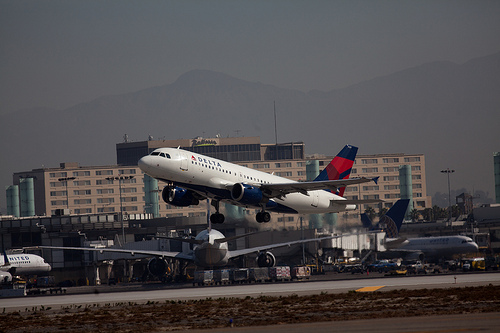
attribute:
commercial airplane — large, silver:
[22, 213, 384, 270]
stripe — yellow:
[353, 281, 385, 296]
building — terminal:
[3, 210, 312, 292]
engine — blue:
[111, 183, 242, 237]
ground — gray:
[443, 140, 458, 163]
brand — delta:
[191, 149, 222, 174]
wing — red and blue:
[259, 174, 380, 200]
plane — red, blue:
[130, 129, 390, 223]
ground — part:
[2, 287, 496, 318]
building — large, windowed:
[7, 128, 433, 234]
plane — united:
[384, 228, 484, 272]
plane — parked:
[137, 140, 377, 226]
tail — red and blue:
[313, 143, 358, 196]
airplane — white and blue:
[132, 112, 400, 234]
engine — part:
[227, 179, 272, 209]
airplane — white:
[380, 216, 477, 254]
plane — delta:
[137, 138, 361, 234]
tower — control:
[167, 140, 307, 162]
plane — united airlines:
[136, 143, 383, 215]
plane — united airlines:
[20, 201, 384, 277]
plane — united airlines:
[1, 245, 51, 296]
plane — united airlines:
[381, 234, 481, 272]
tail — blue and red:
[308, 156, 410, 233]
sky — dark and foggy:
[3, 0, 499, 220]